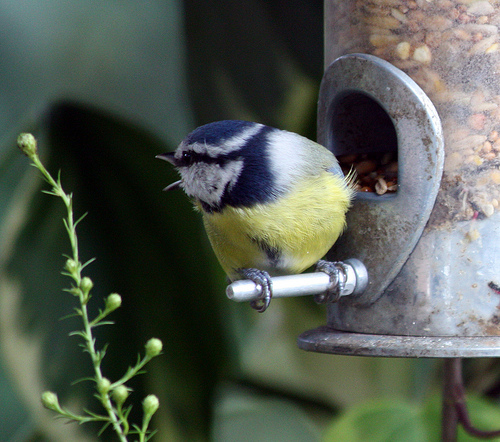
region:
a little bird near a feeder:
[144, 116, 365, 310]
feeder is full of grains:
[321, 3, 498, 354]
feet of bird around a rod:
[221, 258, 358, 314]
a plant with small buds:
[5, 125, 170, 440]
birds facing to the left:
[146, 113, 365, 305]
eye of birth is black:
[174, 138, 203, 175]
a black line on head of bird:
[171, 138, 241, 177]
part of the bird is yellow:
[199, 178, 352, 288]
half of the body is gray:
[144, 110, 347, 202]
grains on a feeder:
[341, 128, 398, 204]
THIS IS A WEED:
[13, 118, 175, 440]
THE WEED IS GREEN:
[13, 123, 178, 438]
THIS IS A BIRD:
[146, 102, 368, 314]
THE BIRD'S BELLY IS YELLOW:
[190, 179, 350, 301]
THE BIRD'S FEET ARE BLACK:
[238, 260, 382, 310]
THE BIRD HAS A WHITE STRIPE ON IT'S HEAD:
[169, 112, 272, 174]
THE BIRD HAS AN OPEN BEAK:
[153, 148, 185, 203]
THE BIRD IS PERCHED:
[148, 117, 362, 321]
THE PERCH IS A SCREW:
[223, 248, 393, 328]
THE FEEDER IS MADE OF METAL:
[222, 5, 499, 378]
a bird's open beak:
[150, 145, 183, 197]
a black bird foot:
[309, 254, 354, 307]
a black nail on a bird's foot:
[258, 295, 270, 316]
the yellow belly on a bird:
[236, 175, 349, 269]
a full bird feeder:
[292, 0, 492, 360]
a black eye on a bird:
[176, 146, 191, 161]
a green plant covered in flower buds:
[7, 125, 177, 437]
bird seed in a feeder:
[343, 152, 390, 187]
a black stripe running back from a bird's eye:
[190, 146, 249, 166]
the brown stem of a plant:
[436, 357, 474, 438]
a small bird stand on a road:
[148, 109, 362, 308]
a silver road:
[219, 263, 358, 313]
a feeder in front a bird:
[146, 5, 498, 377]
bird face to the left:
[134, 106, 362, 311]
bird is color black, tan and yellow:
[145, 114, 360, 305]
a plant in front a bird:
[1, 120, 168, 435]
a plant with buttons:
[7, 129, 169, 431]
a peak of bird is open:
[141, 112, 238, 224]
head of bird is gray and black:
[146, 98, 251, 208]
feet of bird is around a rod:
[207, 254, 351, 316]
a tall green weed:
[20, 133, 161, 435]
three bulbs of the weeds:
[117, 335, 171, 419]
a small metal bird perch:
[222, 251, 366, 313]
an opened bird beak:
[157, 150, 193, 196]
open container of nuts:
[323, 80, 413, 207]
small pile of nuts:
[337, 142, 409, 211]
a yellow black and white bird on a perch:
[158, 121, 367, 303]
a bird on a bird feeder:
[157, 2, 497, 404]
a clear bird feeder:
[325, 2, 498, 338]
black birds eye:
[169, 138, 204, 160]